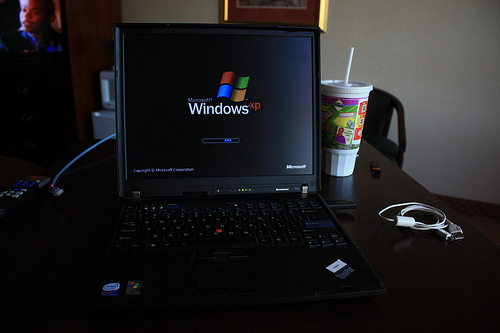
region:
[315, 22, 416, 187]
colorful tall cup with white straw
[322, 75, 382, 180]
plastic up with lid and ridged base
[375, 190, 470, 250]
white cord in loops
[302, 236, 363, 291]
tab for folder on black surface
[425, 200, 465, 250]
metal plugs on end of cord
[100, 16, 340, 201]
screen showing software name and logo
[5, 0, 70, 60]
screen showing face turned to side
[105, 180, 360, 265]
keyboard with red button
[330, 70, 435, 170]
part of chair behind cup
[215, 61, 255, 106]
four squares of moving colors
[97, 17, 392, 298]
An open laptop on a table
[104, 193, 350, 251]
The keyboard on a laptop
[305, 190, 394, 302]
The edge of a laptop on a table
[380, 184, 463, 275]
A white cord on a table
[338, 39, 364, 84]
A straw in a cup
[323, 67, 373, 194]
A plastic cup on a table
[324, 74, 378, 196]
A multi colored plastic cup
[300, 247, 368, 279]
A black and white tag on a laptop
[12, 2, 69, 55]
The image of a person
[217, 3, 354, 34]
A framed picture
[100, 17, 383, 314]
open laptop on table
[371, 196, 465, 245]
white cord on table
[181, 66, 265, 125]
logo on computer screen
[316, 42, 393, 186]
plastic cup with straw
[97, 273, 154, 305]
two stickers on laptop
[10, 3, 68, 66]
television screen against wall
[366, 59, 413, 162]
chair in front of white wall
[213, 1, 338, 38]
picture with gold frame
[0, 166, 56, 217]
remote control with blue buttons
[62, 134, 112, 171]
blue wire behind laptop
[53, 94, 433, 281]
black laptop computer on table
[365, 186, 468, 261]
white computer wires to connect things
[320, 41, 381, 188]
large soft drink cup from a fast food restaurant or store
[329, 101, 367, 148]
colorful design on drink cup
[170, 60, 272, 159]
computer screen indicates Windows xp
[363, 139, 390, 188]
small black item on brown table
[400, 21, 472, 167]
wall is grey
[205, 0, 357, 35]
gold framed picture on wall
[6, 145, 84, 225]
electronic device connection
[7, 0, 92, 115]
television is turned on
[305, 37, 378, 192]
White plastic cup with designs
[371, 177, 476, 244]
White USB cord sitting on table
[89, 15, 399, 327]
Black plastic laptop turned on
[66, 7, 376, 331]
Laptop sitting on table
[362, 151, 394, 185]
Small USB flash drive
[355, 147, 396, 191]
USB flash drive sitting on table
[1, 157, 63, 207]
Black plastic remote control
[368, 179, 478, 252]
White USB cable sitting on brown table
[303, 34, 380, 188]
Soft drink container from fast food restaurant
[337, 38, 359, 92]
White plastic straw